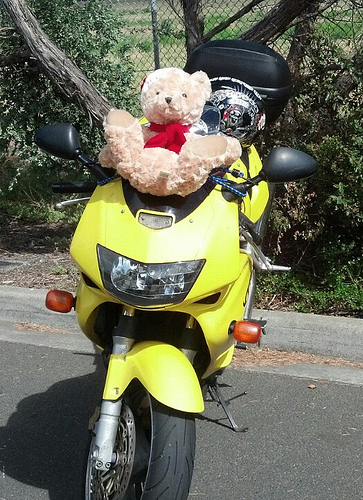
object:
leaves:
[306, 381, 315, 391]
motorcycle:
[33, 41, 318, 499]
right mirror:
[259, 145, 321, 183]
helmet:
[201, 75, 267, 150]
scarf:
[142, 120, 187, 152]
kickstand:
[211, 377, 249, 432]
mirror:
[32, 122, 81, 162]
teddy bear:
[97, 65, 244, 195]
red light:
[232, 321, 263, 343]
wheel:
[82, 390, 196, 499]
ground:
[0, 285, 363, 499]